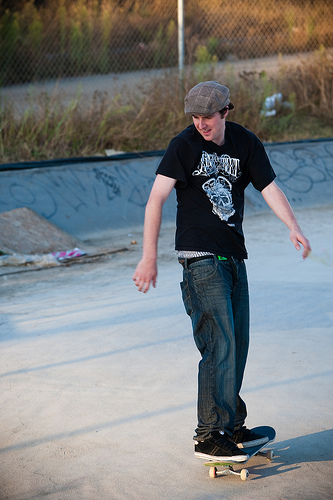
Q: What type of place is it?
A: It is a roadside.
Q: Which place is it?
A: It is a roadside.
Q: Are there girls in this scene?
A: No, there are no girls.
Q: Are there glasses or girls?
A: No, there are no girls or glasses.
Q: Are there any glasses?
A: No, there are no glasses.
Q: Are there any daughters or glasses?
A: No, there are no glasses or daughters.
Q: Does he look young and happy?
A: Yes, the man is young and happy.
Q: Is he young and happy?
A: Yes, the man is young and happy.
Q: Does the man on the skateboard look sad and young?
A: No, the man is young but happy.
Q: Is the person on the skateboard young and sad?
A: No, the man is young but happy.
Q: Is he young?
A: Yes, the man is young.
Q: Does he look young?
A: Yes, the man is young.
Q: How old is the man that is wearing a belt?
A: The man is young.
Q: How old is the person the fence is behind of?
A: The man is young.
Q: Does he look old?
A: No, the man is young.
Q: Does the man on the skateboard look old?
A: No, the man is young.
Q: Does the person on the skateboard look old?
A: No, the man is young.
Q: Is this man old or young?
A: The man is young.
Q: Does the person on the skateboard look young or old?
A: The man is young.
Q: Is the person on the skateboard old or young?
A: The man is young.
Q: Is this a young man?
A: Yes, this is a young man.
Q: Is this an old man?
A: No, this is a young man.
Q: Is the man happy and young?
A: Yes, the man is happy and young.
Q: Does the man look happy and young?
A: Yes, the man is happy and young.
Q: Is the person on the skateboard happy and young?
A: Yes, the man is happy and young.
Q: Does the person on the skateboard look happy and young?
A: Yes, the man is happy and young.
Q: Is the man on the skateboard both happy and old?
A: No, the man is happy but young.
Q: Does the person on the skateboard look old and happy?
A: No, the man is happy but young.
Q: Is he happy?
A: Yes, the man is happy.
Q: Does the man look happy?
A: Yes, the man is happy.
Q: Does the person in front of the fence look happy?
A: Yes, the man is happy.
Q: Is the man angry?
A: No, the man is happy.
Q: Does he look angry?
A: No, the man is happy.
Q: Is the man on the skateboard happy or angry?
A: The man is happy.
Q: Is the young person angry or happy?
A: The man is happy.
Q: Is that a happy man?
A: Yes, that is a happy man.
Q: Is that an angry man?
A: No, that is a happy man.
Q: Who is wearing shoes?
A: The man is wearing shoes.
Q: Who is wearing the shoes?
A: The man is wearing shoes.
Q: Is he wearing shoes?
A: Yes, the man is wearing shoes.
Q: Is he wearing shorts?
A: No, the man is wearing shoes.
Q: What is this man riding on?
A: The man is riding on a skateboard.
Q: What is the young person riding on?
A: The man is riding on a skateboard.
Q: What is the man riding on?
A: The man is riding on a skateboard.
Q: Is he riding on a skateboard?
A: Yes, the man is riding on a skateboard.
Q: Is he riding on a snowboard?
A: No, the man is riding on a skateboard.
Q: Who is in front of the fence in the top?
A: The man is in front of the fence.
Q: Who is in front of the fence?
A: The man is in front of the fence.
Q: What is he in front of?
A: The man is in front of the fence.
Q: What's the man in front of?
A: The man is in front of the fence.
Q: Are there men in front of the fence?
A: Yes, there is a man in front of the fence.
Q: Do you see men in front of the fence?
A: Yes, there is a man in front of the fence.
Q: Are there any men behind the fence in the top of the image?
A: No, the man is in front of the fence.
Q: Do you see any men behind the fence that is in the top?
A: No, the man is in front of the fence.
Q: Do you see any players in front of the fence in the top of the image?
A: No, there is a man in front of the fence.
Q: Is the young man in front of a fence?
A: Yes, the man is in front of a fence.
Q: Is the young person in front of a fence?
A: Yes, the man is in front of a fence.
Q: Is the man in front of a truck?
A: No, the man is in front of a fence.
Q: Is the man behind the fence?
A: No, the man is in front of the fence.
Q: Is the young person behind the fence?
A: No, the man is in front of the fence.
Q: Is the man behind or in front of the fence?
A: The man is in front of the fence.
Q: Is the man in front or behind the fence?
A: The man is in front of the fence.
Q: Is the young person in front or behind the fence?
A: The man is in front of the fence.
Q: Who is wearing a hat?
A: The man is wearing a hat.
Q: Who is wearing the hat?
A: The man is wearing a hat.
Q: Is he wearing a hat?
A: Yes, the man is wearing a hat.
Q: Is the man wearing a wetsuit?
A: No, the man is wearing a hat.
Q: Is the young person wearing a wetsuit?
A: No, the man is wearing a hat.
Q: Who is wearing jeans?
A: The man is wearing jeans.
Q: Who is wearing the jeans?
A: The man is wearing jeans.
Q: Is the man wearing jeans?
A: Yes, the man is wearing jeans.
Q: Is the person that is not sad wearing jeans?
A: Yes, the man is wearing jeans.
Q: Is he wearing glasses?
A: No, the man is wearing jeans.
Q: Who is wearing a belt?
A: The man is wearing a belt.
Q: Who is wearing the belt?
A: The man is wearing a belt.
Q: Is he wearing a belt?
A: Yes, the man is wearing a belt.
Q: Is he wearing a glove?
A: No, the man is wearing a belt.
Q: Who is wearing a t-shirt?
A: The man is wearing a t-shirt.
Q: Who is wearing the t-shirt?
A: The man is wearing a t-shirt.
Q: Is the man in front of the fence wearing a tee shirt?
A: Yes, the man is wearing a tee shirt.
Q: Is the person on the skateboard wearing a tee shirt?
A: Yes, the man is wearing a tee shirt.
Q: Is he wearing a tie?
A: No, the man is wearing a tee shirt.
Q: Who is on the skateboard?
A: The man is on the skateboard.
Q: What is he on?
A: The man is on the skateboard.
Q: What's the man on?
A: The man is on the skateboard.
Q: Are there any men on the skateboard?
A: Yes, there is a man on the skateboard.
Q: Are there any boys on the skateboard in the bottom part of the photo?
A: No, there is a man on the skateboard.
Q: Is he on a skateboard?
A: Yes, the man is on a skateboard.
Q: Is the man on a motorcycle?
A: No, the man is on a skateboard.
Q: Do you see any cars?
A: No, there are no cars.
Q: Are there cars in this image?
A: No, there are no cars.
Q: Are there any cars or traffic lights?
A: No, there are no cars or traffic lights.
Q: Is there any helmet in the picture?
A: No, there are no helmets.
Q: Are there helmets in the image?
A: No, there are no helmets.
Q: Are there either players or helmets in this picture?
A: No, there are no helmets or players.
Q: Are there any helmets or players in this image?
A: No, there are no helmets or players.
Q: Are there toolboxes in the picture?
A: No, there are no toolboxes.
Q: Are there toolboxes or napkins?
A: No, there are no toolboxes or napkins.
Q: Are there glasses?
A: No, there are no glasses.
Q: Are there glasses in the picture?
A: No, there are no glasses.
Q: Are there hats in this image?
A: Yes, there is a hat.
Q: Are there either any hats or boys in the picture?
A: Yes, there is a hat.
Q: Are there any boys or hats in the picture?
A: Yes, there is a hat.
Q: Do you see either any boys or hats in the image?
A: Yes, there is a hat.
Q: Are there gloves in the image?
A: No, there are no gloves.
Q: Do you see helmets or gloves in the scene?
A: No, there are no gloves or helmets.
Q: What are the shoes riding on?
A: The shoes are riding on a skateboard.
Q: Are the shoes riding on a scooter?
A: No, the shoes are riding on a skateboard.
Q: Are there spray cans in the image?
A: No, there are no spray cans.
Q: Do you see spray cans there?
A: No, there are no spray cans.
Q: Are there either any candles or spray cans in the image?
A: No, there are no spray cans or candles.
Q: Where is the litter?
A: The litter is on the roadside.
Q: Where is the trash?
A: The litter is on the roadside.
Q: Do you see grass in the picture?
A: Yes, there is grass.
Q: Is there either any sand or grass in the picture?
A: Yes, there is grass.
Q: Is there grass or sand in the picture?
A: Yes, there is grass.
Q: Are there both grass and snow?
A: No, there is grass but no snow.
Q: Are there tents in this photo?
A: No, there are no tents.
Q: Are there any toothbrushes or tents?
A: No, there are no tents or toothbrushes.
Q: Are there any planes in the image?
A: No, there are no planes.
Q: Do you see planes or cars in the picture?
A: No, there are no planes or cars.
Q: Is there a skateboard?
A: Yes, there is a skateboard.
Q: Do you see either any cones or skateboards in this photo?
A: Yes, there is a skateboard.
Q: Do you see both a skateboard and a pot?
A: No, there is a skateboard but no pots.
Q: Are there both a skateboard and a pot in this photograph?
A: No, there is a skateboard but no pots.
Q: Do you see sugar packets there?
A: No, there are no sugar packets.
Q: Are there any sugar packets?
A: No, there are no sugar packets.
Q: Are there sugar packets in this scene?
A: No, there are no sugar packets.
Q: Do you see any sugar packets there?
A: No, there are no sugar packets.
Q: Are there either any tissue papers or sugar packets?
A: No, there are no sugar packets or tissue papers.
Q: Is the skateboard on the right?
A: Yes, the skateboard is on the right of the image.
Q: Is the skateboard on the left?
A: No, the skateboard is on the right of the image.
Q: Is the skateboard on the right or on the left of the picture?
A: The skateboard is on the right of the image.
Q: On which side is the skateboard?
A: The skateboard is on the right of the image.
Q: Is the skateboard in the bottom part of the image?
A: Yes, the skateboard is in the bottom of the image.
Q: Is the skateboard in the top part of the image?
A: No, the skateboard is in the bottom of the image.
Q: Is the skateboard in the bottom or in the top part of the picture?
A: The skateboard is in the bottom of the image.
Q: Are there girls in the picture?
A: No, there are no girls.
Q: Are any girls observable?
A: No, there are no girls.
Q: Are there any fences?
A: Yes, there is a fence.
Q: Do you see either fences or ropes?
A: Yes, there is a fence.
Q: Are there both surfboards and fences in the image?
A: No, there is a fence but no surfboards.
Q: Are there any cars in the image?
A: No, there are no cars.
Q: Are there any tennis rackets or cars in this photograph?
A: No, there are no cars or tennis rackets.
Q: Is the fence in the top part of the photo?
A: Yes, the fence is in the top of the image.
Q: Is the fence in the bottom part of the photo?
A: No, the fence is in the top of the image.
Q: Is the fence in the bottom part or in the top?
A: The fence is in the top of the image.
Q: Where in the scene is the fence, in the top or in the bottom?
A: The fence is in the top of the image.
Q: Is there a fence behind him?
A: Yes, there is a fence behind the man.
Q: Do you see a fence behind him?
A: Yes, there is a fence behind the man.